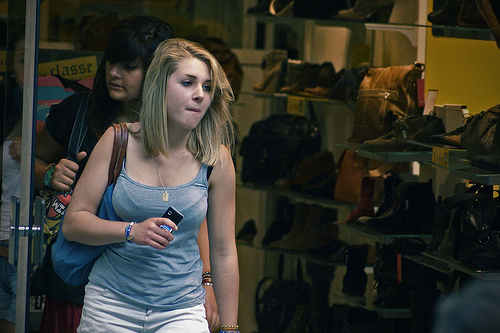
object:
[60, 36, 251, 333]
girl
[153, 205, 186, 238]
cell phone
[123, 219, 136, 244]
bracelet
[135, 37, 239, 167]
hair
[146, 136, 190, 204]
necklace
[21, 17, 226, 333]
woman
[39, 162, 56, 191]
watch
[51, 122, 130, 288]
bag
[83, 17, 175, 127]
hair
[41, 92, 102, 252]
purse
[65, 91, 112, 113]
shoulder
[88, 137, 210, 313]
tank top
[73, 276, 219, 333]
pants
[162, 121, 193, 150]
neck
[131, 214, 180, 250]
hand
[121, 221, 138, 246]
wrist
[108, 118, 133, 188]
strap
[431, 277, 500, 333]
head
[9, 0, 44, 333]
door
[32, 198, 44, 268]
handle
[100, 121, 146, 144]
shoulder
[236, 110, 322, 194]
purse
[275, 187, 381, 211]
shelf